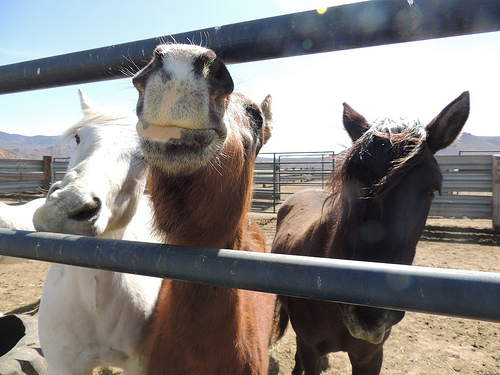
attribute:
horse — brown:
[122, 41, 280, 373]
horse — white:
[13, 90, 176, 371]